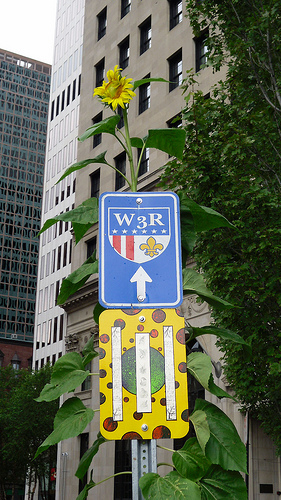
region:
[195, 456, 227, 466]
edge of a leaf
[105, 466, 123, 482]
part of a stalk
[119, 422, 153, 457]
edge of a board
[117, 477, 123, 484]
part of a door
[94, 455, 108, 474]
part of a wall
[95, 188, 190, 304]
Blue and white sign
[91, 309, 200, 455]
Yellow, green, red, and white sign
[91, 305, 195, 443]
yellow sign with red circles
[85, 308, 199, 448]
Yellow sign with white stripes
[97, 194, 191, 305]
Blue sign with white arrow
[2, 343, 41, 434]
red brick on building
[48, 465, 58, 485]
red sign in window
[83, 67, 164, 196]
Large yellow flower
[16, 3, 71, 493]
Tall white building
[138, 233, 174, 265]
Fur de les symbol on sign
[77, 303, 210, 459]
Yellow signs with polkadots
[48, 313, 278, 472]
Ivy growing up street sign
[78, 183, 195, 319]
Blue sign with symbol and arrow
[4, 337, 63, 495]
Bunch of small trees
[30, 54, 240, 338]
Very tall sunflower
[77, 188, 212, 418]
Colorful street sign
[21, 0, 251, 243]
Tall grey building with many windows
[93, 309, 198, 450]
Three white lines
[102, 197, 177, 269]
Representation of a flag on sign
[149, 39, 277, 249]
Branches with green leaves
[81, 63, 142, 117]
the flower is yellow.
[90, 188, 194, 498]
two signs on a pole.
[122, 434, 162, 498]
the pole is metal.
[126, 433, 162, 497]
the pole is silver.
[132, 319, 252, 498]
the leaves are green.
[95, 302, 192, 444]
the sign is yellow.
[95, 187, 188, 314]
the sign is blue.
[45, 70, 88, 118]
line of windows on building.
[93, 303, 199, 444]
the sign is rectangle.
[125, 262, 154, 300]
white arrow pointing up.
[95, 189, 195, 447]
A sign with colorful displays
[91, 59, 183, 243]
a sunflower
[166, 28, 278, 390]
a large tree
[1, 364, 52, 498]
a smaller tree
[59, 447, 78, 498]
meters attached to a building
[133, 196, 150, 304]
rivets holding a sign in place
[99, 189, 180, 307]
A blue sign with an arrow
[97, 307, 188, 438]
a yellow sign with green and red circles and white lines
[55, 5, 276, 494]
A large office building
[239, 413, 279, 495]
the entrance to a building